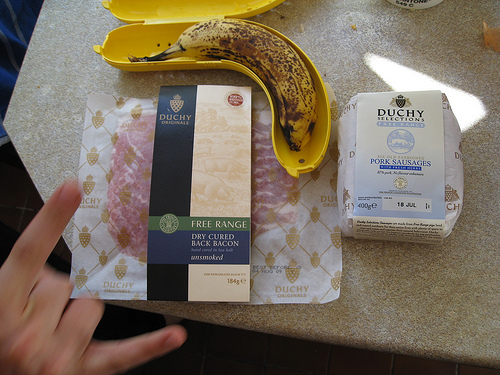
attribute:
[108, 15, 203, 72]
holder — banana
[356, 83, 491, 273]
sausages — made, packed, boxed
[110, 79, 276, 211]
bacon — back, made, dry, packed, here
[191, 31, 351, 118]
banana — here, crescent-shaped, unpeeled, ripe, brown, fruit, sickle-shaped, yellow, black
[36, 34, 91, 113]
countertop — beige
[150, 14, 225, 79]
case — shaped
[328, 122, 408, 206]
packaging — dated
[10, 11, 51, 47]
floor — tile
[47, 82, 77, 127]
table — grey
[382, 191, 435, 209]
date — black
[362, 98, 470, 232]
package — unopened, small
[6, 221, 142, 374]
hand — next, small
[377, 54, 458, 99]
light — sun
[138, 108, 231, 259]
package — black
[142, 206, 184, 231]
logo — round